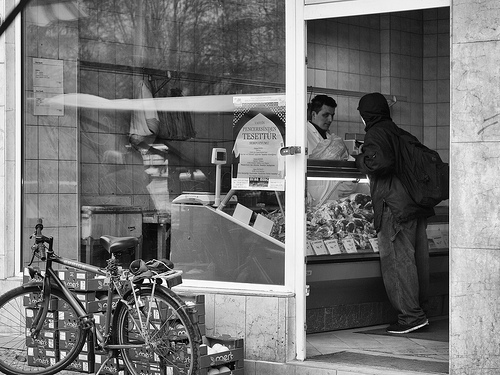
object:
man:
[357, 91, 448, 334]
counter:
[168, 158, 452, 334]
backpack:
[373, 123, 453, 206]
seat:
[98, 234, 139, 253]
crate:
[26, 345, 61, 367]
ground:
[2, 344, 499, 373]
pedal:
[77, 314, 95, 331]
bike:
[1, 218, 199, 374]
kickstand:
[94, 353, 114, 375]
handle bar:
[35, 217, 46, 260]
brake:
[27, 243, 41, 267]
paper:
[33, 55, 66, 118]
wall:
[451, 21, 500, 278]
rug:
[305, 349, 447, 373]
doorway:
[306, 7, 448, 374]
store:
[24, 0, 447, 374]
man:
[305, 94, 352, 161]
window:
[24, 0, 285, 284]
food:
[274, 193, 382, 255]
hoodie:
[352, 92, 436, 232]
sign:
[231, 94, 288, 191]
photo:
[1, 0, 499, 374]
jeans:
[374, 203, 430, 335]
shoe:
[386, 309, 429, 333]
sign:
[341, 235, 360, 254]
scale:
[170, 145, 241, 207]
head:
[356, 93, 392, 125]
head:
[309, 94, 338, 132]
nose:
[328, 114, 333, 123]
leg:
[415, 205, 429, 318]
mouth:
[325, 123, 331, 125]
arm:
[351, 129, 393, 174]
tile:
[97, 71, 117, 100]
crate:
[60, 348, 93, 373]